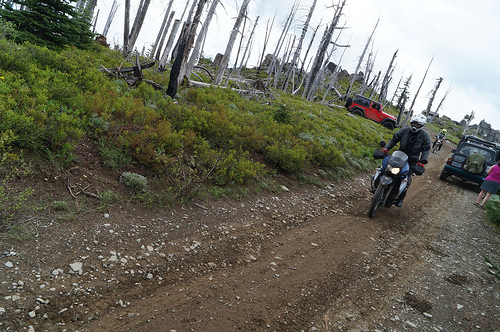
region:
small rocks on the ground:
[36, 255, 129, 297]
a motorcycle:
[365, 159, 410, 216]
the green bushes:
[63, 91, 205, 144]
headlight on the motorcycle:
[382, 161, 397, 172]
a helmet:
[405, 110, 425, 123]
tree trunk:
[220, 21, 295, 92]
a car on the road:
[452, 131, 487, 178]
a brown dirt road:
[266, 202, 376, 293]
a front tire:
[362, 180, 387, 220]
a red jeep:
[347, 88, 394, 128]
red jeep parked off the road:
[342, 85, 395, 128]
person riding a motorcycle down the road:
[359, 88, 441, 223]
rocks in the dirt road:
[51, 232, 199, 304]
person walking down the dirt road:
[474, 155, 499, 209]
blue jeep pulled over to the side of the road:
[442, 138, 495, 183]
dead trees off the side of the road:
[221, 12, 324, 96]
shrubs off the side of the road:
[39, 63, 144, 160]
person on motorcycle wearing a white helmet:
[406, 109, 431, 134]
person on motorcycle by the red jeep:
[431, 122, 451, 156]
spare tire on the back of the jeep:
[456, 145, 486, 175]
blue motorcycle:
[362, 144, 423, 216]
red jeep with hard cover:
[345, 87, 399, 141]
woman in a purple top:
[487, 161, 498, 204]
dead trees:
[192, 6, 358, 84]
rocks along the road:
[27, 200, 341, 301]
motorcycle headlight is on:
[381, 158, 407, 180]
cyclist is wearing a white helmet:
[394, 101, 433, 136]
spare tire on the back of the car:
[463, 149, 494, 186]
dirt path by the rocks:
[153, 216, 391, 324]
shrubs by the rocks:
[72, 86, 272, 191]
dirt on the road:
[14, 210, 159, 274]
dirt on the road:
[197, 214, 280, 259]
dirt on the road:
[355, 243, 443, 313]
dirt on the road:
[93, 150, 240, 249]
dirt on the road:
[308, 229, 466, 319]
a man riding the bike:
[355, 95, 442, 259]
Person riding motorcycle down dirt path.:
[363, 110, 433, 222]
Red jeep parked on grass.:
[343, 88, 399, 130]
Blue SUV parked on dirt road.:
[438, 136, 498, 191]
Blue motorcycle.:
[365, 140, 427, 217]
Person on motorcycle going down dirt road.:
[431, 127, 448, 155]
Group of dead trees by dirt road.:
[90, 0, 448, 125]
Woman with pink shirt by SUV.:
[474, 151, 498, 209]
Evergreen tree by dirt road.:
[0, 0, 98, 63]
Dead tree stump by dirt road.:
[161, 16, 195, 100]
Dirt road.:
[0, 148, 498, 330]